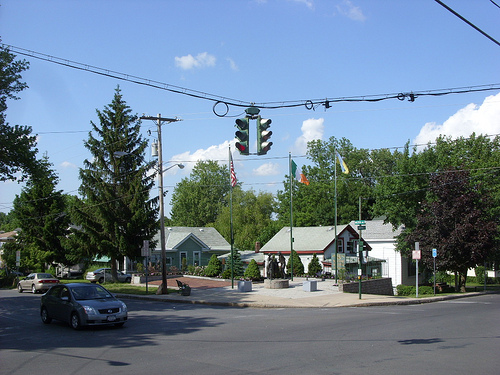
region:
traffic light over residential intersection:
[10, 15, 485, 365]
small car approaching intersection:
[5, 260, 490, 370]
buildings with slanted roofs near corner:
[136, 215, 381, 305]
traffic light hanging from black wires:
[15, 40, 491, 155]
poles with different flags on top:
[220, 135, 350, 285]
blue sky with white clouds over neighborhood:
[3, 2, 495, 217]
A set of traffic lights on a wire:
[232, 110, 271, 155]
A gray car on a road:
[40, 283, 125, 325]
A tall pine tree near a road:
[70, 83, 164, 271]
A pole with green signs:
[352, 203, 369, 295]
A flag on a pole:
[283, 150, 301, 279]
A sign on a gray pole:
[404, 240, 422, 297]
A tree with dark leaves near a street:
[403, 165, 488, 290]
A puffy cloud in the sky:
[172, 45, 238, 74]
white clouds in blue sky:
[38, 100, 85, 123]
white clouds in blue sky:
[143, 32, 200, 85]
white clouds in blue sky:
[205, 29, 275, 63]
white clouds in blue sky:
[278, 40, 359, 85]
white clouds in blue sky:
[323, 29, 395, 76]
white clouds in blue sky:
[379, 115, 419, 147]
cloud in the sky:
[155, 40, 231, 76]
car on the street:
[20, 266, 135, 331]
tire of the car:
[55, 300, 90, 332]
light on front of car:
[71, 299, 103, 322]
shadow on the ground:
[160, 302, 227, 347]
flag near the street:
[269, 142, 323, 202]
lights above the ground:
[208, 98, 289, 168]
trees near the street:
[290, 126, 484, 231]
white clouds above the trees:
[408, 81, 491, 135]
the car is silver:
[42, 285, 134, 325]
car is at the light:
[42, 282, 139, 341]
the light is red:
[237, 144, 247, 156]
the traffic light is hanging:
[229, 98, 279, 158]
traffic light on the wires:
[225, 90, 302, 178]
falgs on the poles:
[218, 148, 353, 185]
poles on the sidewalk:
[222, 167, 363, 303]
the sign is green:
[330, 253, 346, 273]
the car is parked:
[25, 270, 57, 298]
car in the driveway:
[84, 262, 138, 284]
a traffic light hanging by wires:
[6, 45, 498, 167]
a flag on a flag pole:
[285, 147, 310, 282]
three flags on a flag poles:
[215, 145, 351, 292]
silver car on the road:
[33, 279, 130, 333]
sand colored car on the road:
[13, 269, 60, 294]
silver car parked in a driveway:
[85, 265, 129, 283]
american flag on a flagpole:
[226, 145, 238, 193]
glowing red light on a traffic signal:
[233, 139, 250, 152]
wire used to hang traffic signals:
[3, 41, 499, 118]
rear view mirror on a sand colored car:
[20, 275, 27, 281]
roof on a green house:
[134, 220, 231, 254]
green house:
[111, 214, 236, 279]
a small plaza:
[187, 267, 387, 312]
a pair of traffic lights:
[227, 106, 284, 156]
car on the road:
[35, 271, 147, 341]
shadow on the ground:
[12, 280, 225, 372]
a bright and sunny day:
[12, 12, 490, 356]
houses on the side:
[49, 190, 426, 295]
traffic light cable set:
[16, 30, 493, 140]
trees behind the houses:
[168, 117, 498, 235]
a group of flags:
[210, 134, 365, 264]